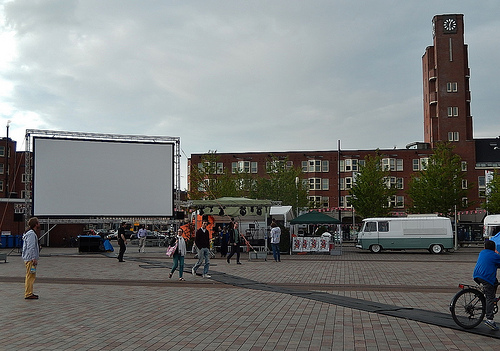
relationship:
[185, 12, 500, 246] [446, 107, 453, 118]
building with window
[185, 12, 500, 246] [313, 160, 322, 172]
building with window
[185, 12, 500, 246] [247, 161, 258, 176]
building with window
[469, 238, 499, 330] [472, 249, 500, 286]
boy wearing jacket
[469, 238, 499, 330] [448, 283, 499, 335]
boy riding bicycle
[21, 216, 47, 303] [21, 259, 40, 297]
man wearing pants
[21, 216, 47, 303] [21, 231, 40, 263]
man in shirt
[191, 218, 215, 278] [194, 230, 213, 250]
man in sweater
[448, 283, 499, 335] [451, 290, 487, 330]
bicycle has spokes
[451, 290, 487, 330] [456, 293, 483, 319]
spokes with spokes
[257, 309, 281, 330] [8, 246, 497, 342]
tile on ground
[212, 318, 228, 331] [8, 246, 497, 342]
tile on ground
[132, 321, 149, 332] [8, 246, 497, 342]
tile on ground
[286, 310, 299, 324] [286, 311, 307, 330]
line in tile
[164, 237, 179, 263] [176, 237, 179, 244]
bag over shoulder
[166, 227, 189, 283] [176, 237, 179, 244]
woman has shoulder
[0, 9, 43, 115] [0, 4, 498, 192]
cloud in sky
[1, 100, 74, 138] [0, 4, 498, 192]
cloud in sky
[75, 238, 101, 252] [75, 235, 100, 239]
table with top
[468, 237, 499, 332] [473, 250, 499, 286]
person in jacket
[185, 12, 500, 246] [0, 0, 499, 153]
building in background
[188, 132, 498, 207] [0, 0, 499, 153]
trees in background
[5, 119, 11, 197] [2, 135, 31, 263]
smokestack on building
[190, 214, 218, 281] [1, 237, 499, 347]
person on street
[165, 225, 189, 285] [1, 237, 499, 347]
person on street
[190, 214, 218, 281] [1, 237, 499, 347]
person walking on street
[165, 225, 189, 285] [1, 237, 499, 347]
person walking on street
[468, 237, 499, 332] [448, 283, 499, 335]
person riding bicycle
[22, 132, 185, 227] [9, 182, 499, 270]
billboard in center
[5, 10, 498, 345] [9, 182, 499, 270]
town has center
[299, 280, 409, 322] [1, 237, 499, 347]
mat on street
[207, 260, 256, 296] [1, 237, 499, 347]
mat on street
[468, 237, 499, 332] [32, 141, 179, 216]
person leaving screen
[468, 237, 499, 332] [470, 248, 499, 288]
person in blue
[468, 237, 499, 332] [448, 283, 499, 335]
person has bicycle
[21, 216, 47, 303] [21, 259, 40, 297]
person in pants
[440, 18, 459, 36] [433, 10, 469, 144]
clock top of tower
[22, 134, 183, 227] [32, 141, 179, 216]
frame around screen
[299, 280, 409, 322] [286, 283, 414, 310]
mat covers cables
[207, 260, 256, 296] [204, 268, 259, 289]
mat covers cables